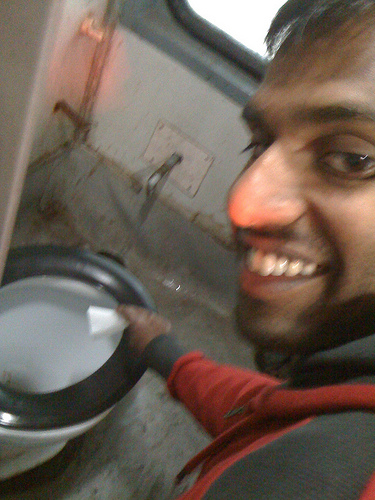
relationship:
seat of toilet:
[45, 255, 96, 276] [2, 255, 140, 406]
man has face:
[215, 5, 374, 495] [259, 66, 348, 306]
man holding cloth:
[215, 5, 374, 495] [91, 311, 108, 326]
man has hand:
[215, 5, 374, 495] [137, 315, 164, 336]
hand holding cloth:
[137, 315, 164, 336] [91, 311, 108, 326]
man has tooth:
[215, 5, 374, 495] [293, 263, 296, 274]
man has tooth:
[215, 5, 374, 495] [265, 260, 271, 276]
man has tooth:
[215, 5, 374, 495] [248, 255, 252, 268]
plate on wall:
[178, 144, 201, 171] [130, 68, 183, 117]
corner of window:
[192, 2, 204, 18] [226, 3, 261, 32]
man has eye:
[215, 5, 374, 495] [327, 142, 374, 176]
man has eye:
[215, 5, 374, 495] [244, 138, 266, 153]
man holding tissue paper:
[215, 5, 374, 495] [93, 310, 116, 326]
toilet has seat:
[2, 255, 140, 406] [45, 255, 96, 276]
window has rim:
[226, 3, 261, 32] [222, 41, 239, 55]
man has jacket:
[215, 5, 374, 495] [215, 383, 344, 491]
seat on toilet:
[45, 255, 96, 276] [2, 255, 140, 406]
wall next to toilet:
[130, 68, 183, 117] [2, 255, 140, 406]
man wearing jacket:
[215, 5, 374, 495] [215, 383, 344, 491]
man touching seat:
[215, 5, 374, 495] [45, 255, 96, 276]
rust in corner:
[52, 197, 60, 211] [48, 179, 57, 183]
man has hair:
[215, 5, 374, 495] [287, 5, 301, 14]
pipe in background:
[148, 177, 160, 186] [58, 93, 92, 168]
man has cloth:
[215, 5, 374, 495] [91, 311, 108, 326]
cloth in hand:
[91, 311, 108, 326] [137, 315, 164, 336]